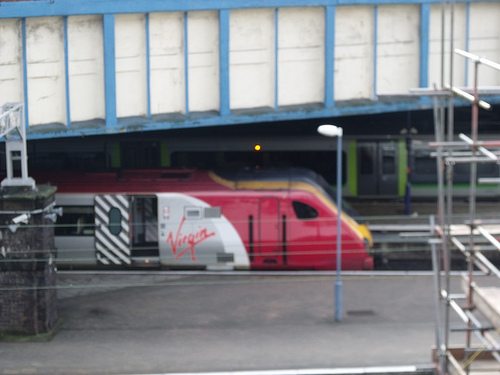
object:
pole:
[333, 126, 343, 322]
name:
[165, 216, 215, 261]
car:
[0, 166, 373, 269]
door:
[93, 192, 133, 269]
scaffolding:
[400, 44, 500, 375]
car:
[55, 191, 251, 273]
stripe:
[204, 166, 373, 251]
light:
[317, 124, 343, 137]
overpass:
[1, 2, 498, 148]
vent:
[347, 309, 373, 316]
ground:
[0, 275, 461, 372]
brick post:
[0, 186, 56, 336]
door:
[378, 140, 400, 195]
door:
[358, 141, 378, 194]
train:
[27, 134, 498, 199]